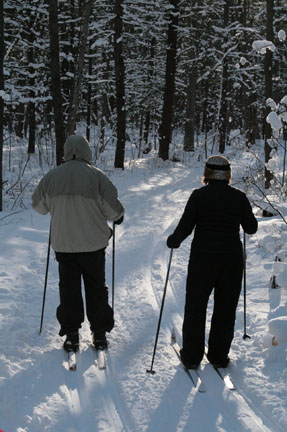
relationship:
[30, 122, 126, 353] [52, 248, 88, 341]
man has leg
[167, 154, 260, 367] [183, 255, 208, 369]
lady has leg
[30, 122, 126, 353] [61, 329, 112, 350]
man has feet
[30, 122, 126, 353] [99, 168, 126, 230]
man has arm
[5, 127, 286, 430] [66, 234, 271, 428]
snow has tracks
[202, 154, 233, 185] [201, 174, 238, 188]
hat covers hair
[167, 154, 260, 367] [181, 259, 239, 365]
lady wears pants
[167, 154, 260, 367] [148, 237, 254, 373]
lady holds poles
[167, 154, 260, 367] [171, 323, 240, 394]
lady has skiis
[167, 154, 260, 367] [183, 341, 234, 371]
lady has boots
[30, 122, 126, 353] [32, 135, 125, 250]
man wears jacket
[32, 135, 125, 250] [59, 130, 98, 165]
jacket has hood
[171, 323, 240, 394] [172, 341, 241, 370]
skiis on feet